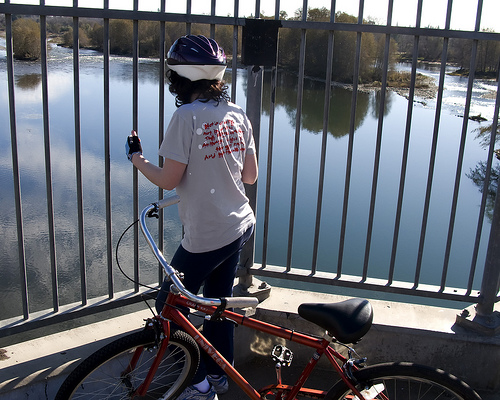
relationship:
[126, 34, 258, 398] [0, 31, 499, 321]
person looking at water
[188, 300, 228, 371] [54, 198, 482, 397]
writing on side of bike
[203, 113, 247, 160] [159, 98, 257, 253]
writing on back of shirt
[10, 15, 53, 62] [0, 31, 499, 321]
tree in water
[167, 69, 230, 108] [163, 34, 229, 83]
hair beneath helmet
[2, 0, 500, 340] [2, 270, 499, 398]
fence beneath concrete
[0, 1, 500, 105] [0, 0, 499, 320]
trees in background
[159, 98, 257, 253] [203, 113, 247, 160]
shirt with writing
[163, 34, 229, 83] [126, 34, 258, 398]
helmet on top of person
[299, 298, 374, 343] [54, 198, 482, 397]
seat on top of bike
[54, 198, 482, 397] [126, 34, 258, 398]
bike behind person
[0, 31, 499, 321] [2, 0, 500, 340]
water in front of fence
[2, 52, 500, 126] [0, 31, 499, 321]
reflection in water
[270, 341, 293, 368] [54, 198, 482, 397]
petal on side of bike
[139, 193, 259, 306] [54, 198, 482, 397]
handlebars in front of bike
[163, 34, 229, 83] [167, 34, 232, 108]
helmet on top of head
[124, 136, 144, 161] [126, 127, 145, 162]
glove surrounding hand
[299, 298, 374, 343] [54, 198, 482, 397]
seat attached to bike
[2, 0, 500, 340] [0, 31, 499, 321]
fence in front of water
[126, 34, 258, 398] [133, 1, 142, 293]
person gripping rail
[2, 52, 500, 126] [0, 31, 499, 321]
reflection on top of water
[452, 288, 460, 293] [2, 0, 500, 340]
bolt holding fence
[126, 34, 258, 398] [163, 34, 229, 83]
person with helmet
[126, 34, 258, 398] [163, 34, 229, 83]
person wearing helmet